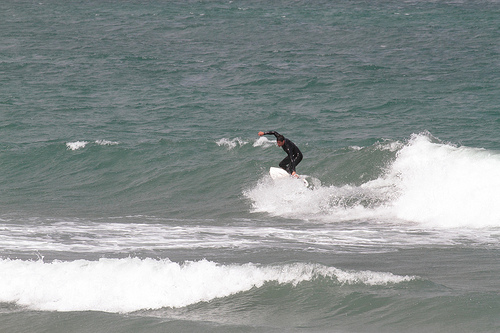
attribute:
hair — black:
[275, 131, 286, 143]